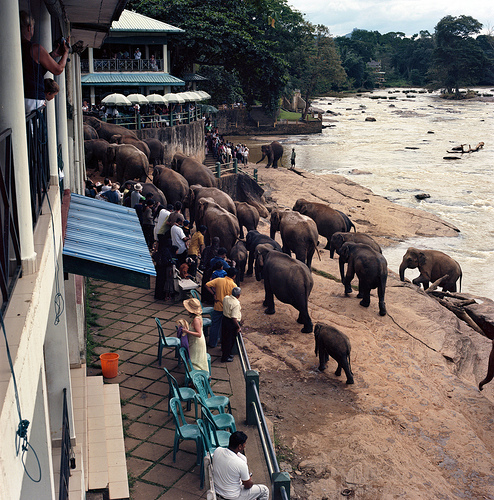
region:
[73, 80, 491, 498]
elephant heard on rocks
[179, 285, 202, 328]
woman wearing straw hat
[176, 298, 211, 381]
woman wearing long dress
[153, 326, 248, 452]
group of green chairs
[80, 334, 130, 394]
orange bucket on sidewalk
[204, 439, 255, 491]
man wearing white shirt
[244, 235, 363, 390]
baby elephant behind adult elephant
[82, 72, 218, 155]
group of umbrellas on deck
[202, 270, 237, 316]
person wearing yellow shirt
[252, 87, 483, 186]
water is dark green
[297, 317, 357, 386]
A baby elephant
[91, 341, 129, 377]
an orange bucket on the ground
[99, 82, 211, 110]
a group of white umbrellas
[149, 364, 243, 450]
a froup of green chairs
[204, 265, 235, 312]
a man in an orange shirt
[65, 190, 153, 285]
a blue tin awning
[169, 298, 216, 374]
a woman wearing a yellow dress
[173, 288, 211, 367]
a woman wearing a tan hat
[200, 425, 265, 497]
a man sitting down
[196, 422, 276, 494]
a man wearing a white shirt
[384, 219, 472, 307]
a elephant coming out of the water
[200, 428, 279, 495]
a man sitting in a chair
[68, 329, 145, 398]
a orange basket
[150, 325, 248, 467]
blue chairs on a deck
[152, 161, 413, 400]
elephants walking on rocks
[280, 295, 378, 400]
a baby elephant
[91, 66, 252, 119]
white umbrellas outside a building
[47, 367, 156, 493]
a white tiled staircase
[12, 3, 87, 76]
someone taking a photo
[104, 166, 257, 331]
people standing on a deck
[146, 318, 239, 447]
plastic blue chairs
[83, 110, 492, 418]
a herd of Asian elephants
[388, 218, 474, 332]
the elephant is stepping out of the river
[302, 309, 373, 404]
a small elephant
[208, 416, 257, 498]
this man is dressed in white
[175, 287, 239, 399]
she is wearing a sun hat and a dress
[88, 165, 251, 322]
the people are gathered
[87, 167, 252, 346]
they are watching the elephants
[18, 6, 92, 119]
this person is recording the elephants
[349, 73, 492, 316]
a rapid flowing river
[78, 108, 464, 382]
a herd of a elephants moving through a town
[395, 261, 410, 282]
the trunk of an elephant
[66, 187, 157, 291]
a blue awning of a building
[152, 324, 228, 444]
blue chairs on a patio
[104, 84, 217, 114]
white umbrellas on a patio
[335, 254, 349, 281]
a trunk of an elephant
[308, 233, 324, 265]
the tail of an elephant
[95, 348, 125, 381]
an orange bucket of on a patio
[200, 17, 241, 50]
the leaves of a tree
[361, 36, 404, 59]
the leaves of a tree